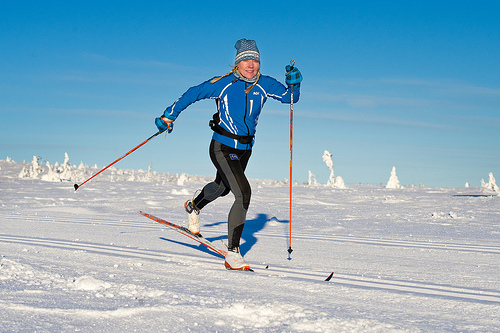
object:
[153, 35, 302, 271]
woman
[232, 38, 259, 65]
beanie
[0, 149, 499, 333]
snow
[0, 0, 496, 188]
sky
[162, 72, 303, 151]
jacket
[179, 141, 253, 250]
pants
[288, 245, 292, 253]
globes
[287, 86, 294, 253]
pole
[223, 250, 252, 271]
shoes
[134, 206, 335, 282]
brake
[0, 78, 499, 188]
cloud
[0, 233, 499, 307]
tracks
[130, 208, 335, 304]
skis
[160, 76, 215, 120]
arm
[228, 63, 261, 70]
hair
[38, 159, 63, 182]
sculptures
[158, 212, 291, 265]
shadow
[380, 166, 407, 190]
triangle